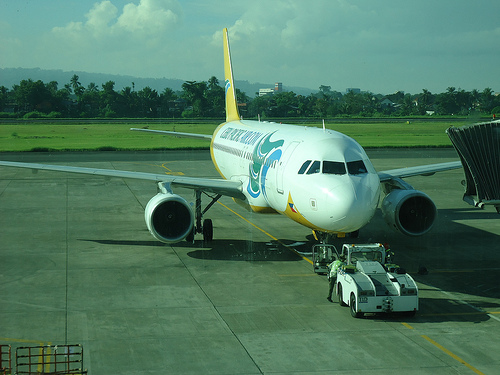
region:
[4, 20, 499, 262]
an airplane sitting on the tarmac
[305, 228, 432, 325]
the vehicle that tows the plane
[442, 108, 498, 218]
the mobile access ramp which connects to the plane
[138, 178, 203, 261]
one of the plane's jet engines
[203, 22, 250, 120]
the yellow tail of the plane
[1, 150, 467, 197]
the wings of the plane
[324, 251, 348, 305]
the driver of the vehicle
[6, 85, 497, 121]
green trees in the background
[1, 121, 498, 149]
a grassy area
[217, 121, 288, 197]
the logo of the airline on the side of the plane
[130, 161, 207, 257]
Jet on the side of wing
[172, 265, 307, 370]
Pavement has a crack in it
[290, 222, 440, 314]
Truck in front of plane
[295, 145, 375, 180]
Windows on front of plane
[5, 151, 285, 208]
Wing on side of plane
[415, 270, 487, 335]
Shadow from the truck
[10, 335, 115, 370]
Metal gate on runway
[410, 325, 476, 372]
Yellow paint on runway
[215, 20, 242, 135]
Tail fin on back of plane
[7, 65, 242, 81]
Mountains behind the trees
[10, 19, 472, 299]
a jet is sitting on the tarmac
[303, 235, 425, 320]
a vehicle is going to pull the plane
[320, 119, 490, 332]
the passenger bridge will attach to the plane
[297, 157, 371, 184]
the windows are in the cockpit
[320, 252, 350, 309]
a worker is getting into the ramp vehicle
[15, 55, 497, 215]
vegetation is behind the airport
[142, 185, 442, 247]
the jet engines of the plane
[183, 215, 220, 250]
the wheels are under the wing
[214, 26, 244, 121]
the tail of the plane is yellow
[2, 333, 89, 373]
a luggage cart is parked nearby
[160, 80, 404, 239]
plane's main color is white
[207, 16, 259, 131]
plane's tail is yellow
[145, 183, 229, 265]
plane has 1 engine on right side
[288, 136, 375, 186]
5 windows on plane's front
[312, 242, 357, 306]
man getting in vehicle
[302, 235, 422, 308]
the vehicle is white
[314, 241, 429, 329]
the vehicle is a truck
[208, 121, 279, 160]
lettering on side of plane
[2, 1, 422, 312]
plane is parked on runway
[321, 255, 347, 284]
man's shirt is yellow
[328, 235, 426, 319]
cargo trolley in front of plane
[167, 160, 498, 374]
yellow line under plane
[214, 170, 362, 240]
white plane with yellow bottom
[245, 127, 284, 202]
green and blue design on side of plane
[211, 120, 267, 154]
dark blue letters on white plane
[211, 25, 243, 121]
yellow tip on white plane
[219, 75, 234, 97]
blue and white logo on yellow tip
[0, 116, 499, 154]
green grass behind concrete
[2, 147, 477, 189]
gray wings spread out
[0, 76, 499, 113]
green trees behind grass